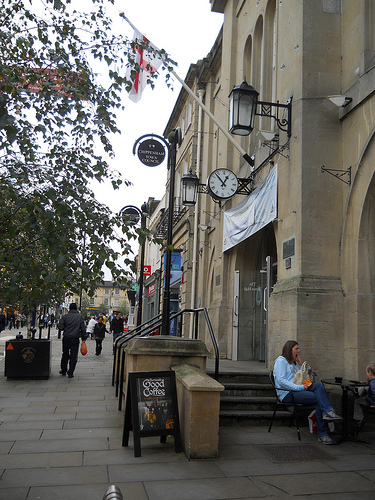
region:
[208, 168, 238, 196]
white and black clock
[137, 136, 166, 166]
metal sign on post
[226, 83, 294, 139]
black metal light on wall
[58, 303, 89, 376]
man holding orange bag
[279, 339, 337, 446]
woman sitting on chair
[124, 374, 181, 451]
store sign on sidewalk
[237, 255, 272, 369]
glass door on building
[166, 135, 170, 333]
black iron sign pole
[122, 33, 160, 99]
white and red flag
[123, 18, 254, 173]
white metal flag pole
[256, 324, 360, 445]
a woman sitting in a chair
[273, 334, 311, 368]
the woman is yawning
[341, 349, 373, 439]
a little boy at the table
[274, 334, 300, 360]
the woman has brown hair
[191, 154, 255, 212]
a clock attached to the building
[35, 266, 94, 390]
person carrying a bag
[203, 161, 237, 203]
the clock numbers are roman numerals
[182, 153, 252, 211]
the clock face is white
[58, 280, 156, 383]
people walking down the street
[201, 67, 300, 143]
the light is off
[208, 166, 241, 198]
Round clock mounted on the side of building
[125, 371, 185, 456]
Standing sign on the ground advertising Good Coffee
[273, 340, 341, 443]
Brown haired woman in a blue sweater sitting in a chair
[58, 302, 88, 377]
Man in dark clothes carrying an orange bag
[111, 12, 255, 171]
Red and white flag flying above the front of a building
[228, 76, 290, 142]
lantern mounted on the side of building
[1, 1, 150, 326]
Green leaves of the tree overhanging a sidewalk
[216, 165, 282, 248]
White banner hanging over the entrance to a building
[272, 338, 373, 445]
Woman and little boy sitting at a small table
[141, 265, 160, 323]
Store with a red sign hanging over the door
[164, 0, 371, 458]
a substantial dull yellow building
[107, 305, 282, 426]
black handrails on side of stairs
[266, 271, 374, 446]
people sitting at a table near an outer wall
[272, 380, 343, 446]
woman's legs are crossed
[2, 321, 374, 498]
long blocks forming a sidewalk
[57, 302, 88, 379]
man carrying an orange bag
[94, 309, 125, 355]
a couple walking and holding hands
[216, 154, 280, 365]
banner over building's entrance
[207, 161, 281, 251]
clock above banner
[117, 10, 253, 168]
a red and white flag on a pole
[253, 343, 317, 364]
A lady with her hand to her mouth.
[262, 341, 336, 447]
A lady sitting in the chair.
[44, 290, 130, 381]
People walking on the sidewalk.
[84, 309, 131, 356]
A couple holding hands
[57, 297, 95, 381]
A person carrying an orange bag.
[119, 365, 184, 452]
A poster sign by the wall.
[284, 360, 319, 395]
A lady holding her purse.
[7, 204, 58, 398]
A tree on the sidewalk.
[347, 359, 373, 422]
A little boy sitting in the chair across from woman.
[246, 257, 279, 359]
The door to the building is halfway open.